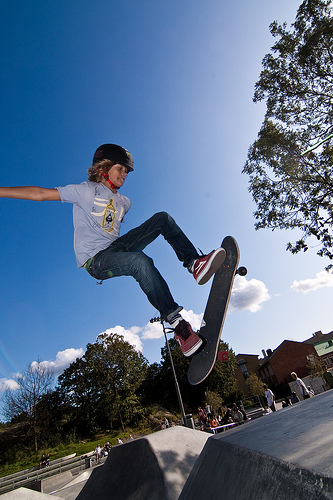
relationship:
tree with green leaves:
[240, 0, 332, 278] [310, 25, 327, 33]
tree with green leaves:
[240, 0, 332, 278] [272, 59, 294, 72]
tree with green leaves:
[240, 0, 332, 278] [297, 81, 323, 99]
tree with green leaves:
[240, 0, 332, 278] [274, 143, 295, 156]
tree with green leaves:
[240, 0, 332, 278] [292, 196, 320, 210]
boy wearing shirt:
[0, 142, 227, 358] [39, 176, 149, 266]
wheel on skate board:
[238, 265, 247, 277] [184, 217, 243, 392]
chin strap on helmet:
[96, 165, 121, 191] [90, 142, 134, 173]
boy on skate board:
[0, 142, 227, 358] [185, 234, 246, 384]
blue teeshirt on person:
[53, 181, 131, 268] [62, 136, 247, 381]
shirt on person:
[258, 390, 277, 408] [257, 380, 279, 416]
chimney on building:
[266, 346, 273, 355] [257, 338, 322, 387]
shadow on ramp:
[158, 442, 200, 480] [77, 391, 330, 496]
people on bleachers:
[195, 406, 238, 421] [195, 399, 266, 434]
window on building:
[233, 353, 254, 380] [224, 319, 330, 407]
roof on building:
[307, 336, 331, 356] [235, 320, 321, 398]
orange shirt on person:
[206, 415, 217, 424] [208, 412, 217, 429]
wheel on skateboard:
[236, 262, 253, 280] [185, 233, 244, 392]